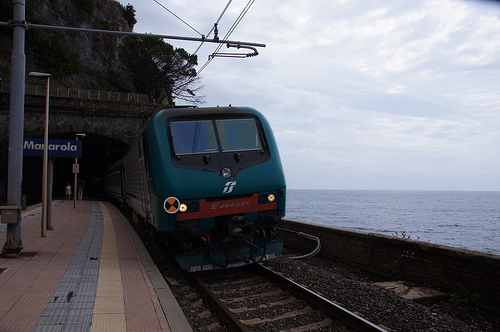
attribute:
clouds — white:
[276, 6, 421, 62]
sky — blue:
[132, 1, 499, 195]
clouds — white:
[374, 90, 474, 182]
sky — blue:
[272, 23, 483, 237]